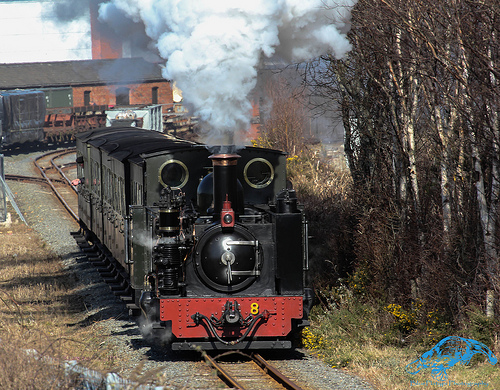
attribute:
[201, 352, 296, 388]
train tracks — dark metal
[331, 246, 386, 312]
flowers — small, yellow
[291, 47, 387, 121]
branches — small, brown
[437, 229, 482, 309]
branches — small, brown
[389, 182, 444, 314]
branches — small, brown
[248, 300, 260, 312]
number eight — yellow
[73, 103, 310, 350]
train — black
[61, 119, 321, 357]
train — black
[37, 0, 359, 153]
smoke — large section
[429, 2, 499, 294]
tree — bare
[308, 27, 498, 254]
trees — bare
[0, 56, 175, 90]
roof — black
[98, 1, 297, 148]
smoke — white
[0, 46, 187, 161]
building — large 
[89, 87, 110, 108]
wall — stone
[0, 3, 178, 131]
building — stone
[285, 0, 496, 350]
tree — wooded 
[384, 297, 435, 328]
flowers — small, yellow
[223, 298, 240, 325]
metal part — red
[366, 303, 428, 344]
flowers — yellow, small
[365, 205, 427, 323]
plant — green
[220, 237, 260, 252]
metal — red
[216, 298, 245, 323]
metal — black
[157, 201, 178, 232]
metal — black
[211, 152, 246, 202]
metal — black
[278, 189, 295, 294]
metal — black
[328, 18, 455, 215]
brown branches — small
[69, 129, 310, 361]
engine — trains